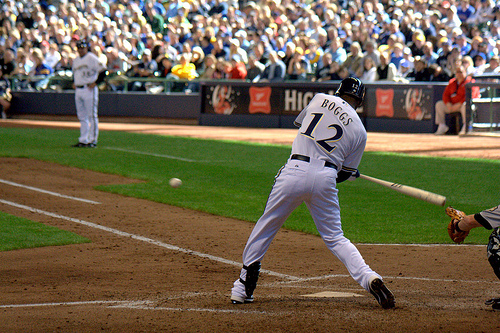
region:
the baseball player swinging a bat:
[230, 76, 445, 308]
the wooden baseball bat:
[357, 172, 445, 206]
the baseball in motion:
[170, 178, 181, 188]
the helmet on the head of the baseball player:
[336, 77, 364, 107]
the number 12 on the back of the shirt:
[300, 112, 344, 153]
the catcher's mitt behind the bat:
[445, 205, 467, 244]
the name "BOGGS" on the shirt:
[321, 98, 353, 125]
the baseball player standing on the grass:
[70, 40, 107, 148]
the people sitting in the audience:
[0, 0, 498, 92]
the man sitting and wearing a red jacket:
[434, 65, 479, 135]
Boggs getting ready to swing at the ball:
[226, 76, 449, 306]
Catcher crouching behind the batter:
[448, 197, 496, 312]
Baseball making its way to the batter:
[168, 173, 181, 191]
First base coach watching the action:
[69, 39, 107, 150]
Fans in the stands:
[4, 0, 498, 84]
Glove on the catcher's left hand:
[446, 201, 472, 249]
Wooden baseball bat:
[351, 163, 446, 205]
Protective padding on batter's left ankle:
[237, 251, 262, 302]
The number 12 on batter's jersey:
[301, 109, 344, 155]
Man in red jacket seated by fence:
[434, 65, 476, 135]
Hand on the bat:
[356, 171, 359, 175]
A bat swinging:
[424, 193, 430, 198]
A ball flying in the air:
[171, 180, 180, 185]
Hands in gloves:
[451, 212, 457, 239]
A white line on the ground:
[288, 275, 293, 280]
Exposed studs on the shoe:
[383, 298, 391, 303]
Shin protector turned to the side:
[250, 268, 255, 286]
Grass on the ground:
[24, 230, 54, 240]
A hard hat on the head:
[345, 80, 360, 92]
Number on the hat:
[351, 83, 358, 88]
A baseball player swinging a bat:
[195, 55, 467, 320]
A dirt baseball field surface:
[90, 200, 235, 260]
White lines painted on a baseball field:
[56, 194, 220, 276]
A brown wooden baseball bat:
[355, 159, 462, 212]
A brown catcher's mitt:
[431, 200, 482, 251]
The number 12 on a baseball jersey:
[298, 108, 359, 158]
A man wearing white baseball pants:
[50, 30, 127, 159]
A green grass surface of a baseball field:
[192, 142, 257, 191]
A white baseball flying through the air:
[164, 166, 191, 197]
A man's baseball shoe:
[353, 265, 405, 317]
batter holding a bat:
[221, 65, 449, 319]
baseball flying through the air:
[168, 173, 184, 191]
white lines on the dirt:
[0, 173, 285, 275]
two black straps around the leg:
[231, 255, 251, 285]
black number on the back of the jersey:
[295, 104, 347, 161]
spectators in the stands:
[0, 0, 498, 92]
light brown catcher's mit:
[443, 204, 465, 241]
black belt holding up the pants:
[288, 150, 337, 176]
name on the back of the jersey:
[319, 94, 355, 134]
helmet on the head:
[332, 73, 365, 102]